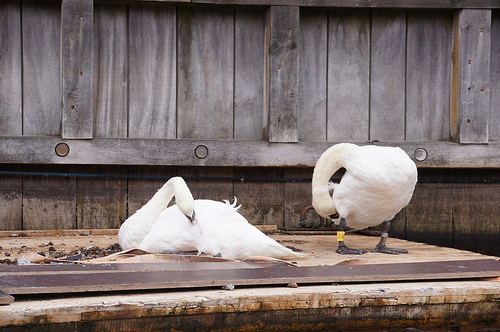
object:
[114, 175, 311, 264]
swan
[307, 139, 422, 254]
swan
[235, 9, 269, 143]
plank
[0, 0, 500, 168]
fence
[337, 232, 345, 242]
tag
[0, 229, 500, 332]
platform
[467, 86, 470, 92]
nail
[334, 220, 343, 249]
legs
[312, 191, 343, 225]
head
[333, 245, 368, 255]
foot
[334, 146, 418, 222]
breast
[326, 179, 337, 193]
tail